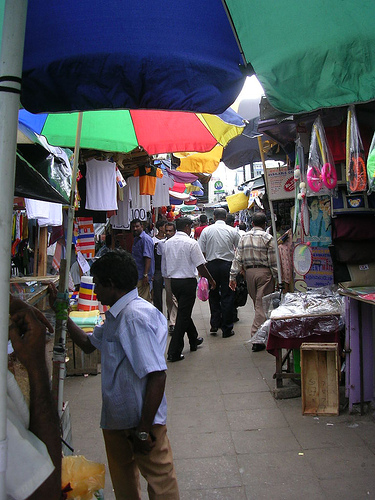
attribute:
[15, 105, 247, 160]
umbrella — colorful, multi-colored, open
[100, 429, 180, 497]
pants — tan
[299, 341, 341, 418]
box — wooden, wood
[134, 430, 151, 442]
watch — silver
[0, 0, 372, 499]
market place — busy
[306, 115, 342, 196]
item — hanging, pink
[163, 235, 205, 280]
shirt — white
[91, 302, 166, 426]
shirt — blue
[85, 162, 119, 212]
shirt — white, hanging, small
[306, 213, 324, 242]
shirt — blue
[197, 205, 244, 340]
person — walking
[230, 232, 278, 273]
shirt — plaid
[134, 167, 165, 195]
shirt — orange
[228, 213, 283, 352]
man — walking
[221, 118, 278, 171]
canopy — black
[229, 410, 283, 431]
stone — square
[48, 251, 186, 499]
man — browsing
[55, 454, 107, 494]
bag — yellow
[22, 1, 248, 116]
fabric — blue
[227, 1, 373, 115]
fabric — green